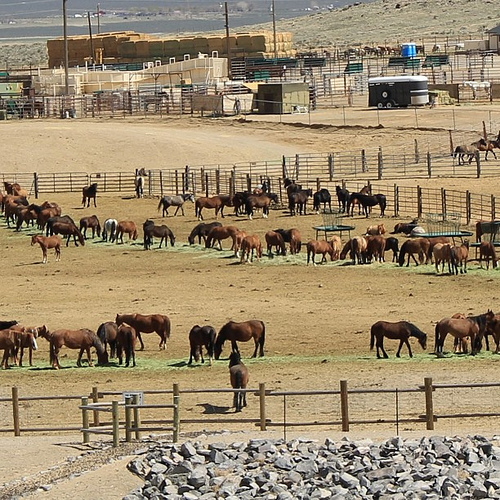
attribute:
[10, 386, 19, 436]
pole — wooden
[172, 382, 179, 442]
pole — wooden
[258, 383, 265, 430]
pole — wooden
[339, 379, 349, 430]
pole — wooden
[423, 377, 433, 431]
pole — wooden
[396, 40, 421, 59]
blue outhouses — portable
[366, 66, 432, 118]
container — round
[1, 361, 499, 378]
grass — green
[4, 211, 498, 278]
grass — green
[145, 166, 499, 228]
fence — metal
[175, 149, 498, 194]
fence — metal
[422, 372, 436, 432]
fence post — wooden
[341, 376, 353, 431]
fence post — wooden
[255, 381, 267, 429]
fence post — wooden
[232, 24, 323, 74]
hay — stacked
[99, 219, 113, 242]
horse — white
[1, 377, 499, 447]
fence — metal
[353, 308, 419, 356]
horse — brown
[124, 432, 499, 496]
rocks — piled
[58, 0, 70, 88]
poles — telephone poles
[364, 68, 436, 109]
horse trailer — green and white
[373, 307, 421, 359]
horse — brown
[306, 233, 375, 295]
horse — brown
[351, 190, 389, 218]
horse — brown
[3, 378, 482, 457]
fence — wooden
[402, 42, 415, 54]
portapotties — blue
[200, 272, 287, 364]
horse — brown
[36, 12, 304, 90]
hay bales — large, rectangular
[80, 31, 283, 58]
hay — large, stacked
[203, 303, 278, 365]
horse — black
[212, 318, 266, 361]
horse — brown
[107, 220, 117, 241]
tail — black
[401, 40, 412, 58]
outhouse — blue, portable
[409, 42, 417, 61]
outhouse — blue, portable